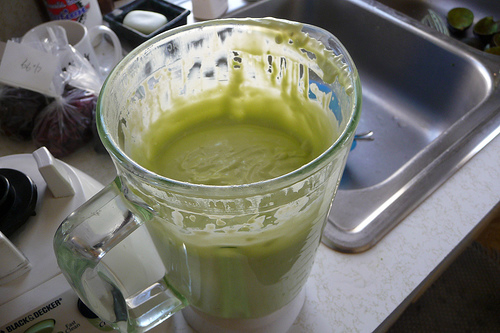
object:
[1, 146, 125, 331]
blender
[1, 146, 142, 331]
blender base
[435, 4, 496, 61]
avocado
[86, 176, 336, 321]
blender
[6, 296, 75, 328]
words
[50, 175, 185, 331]
handle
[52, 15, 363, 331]
pitcher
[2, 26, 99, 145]
bags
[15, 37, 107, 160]
plastic bag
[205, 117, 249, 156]
paste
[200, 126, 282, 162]
avocado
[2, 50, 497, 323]
table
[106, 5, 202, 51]
container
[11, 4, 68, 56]
mug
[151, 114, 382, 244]
cream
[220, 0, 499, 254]
sink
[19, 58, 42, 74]
4.99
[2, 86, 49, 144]
items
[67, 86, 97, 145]
items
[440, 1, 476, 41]
avocado skin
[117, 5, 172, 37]
soap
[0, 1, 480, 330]
counter top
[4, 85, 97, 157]
food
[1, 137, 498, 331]
counter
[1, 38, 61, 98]
tag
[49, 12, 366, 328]
blender